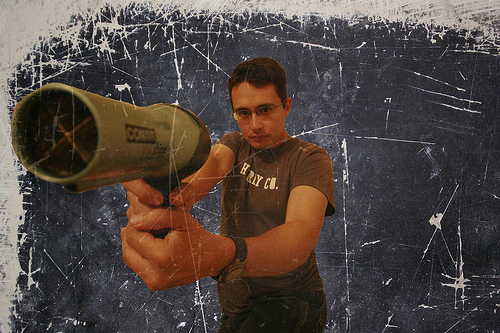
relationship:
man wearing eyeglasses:
[118, 57, 336, 331] [227, 104, 282, 119]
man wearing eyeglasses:
[205, 48, 310, 152] [230, 101, 283, 120]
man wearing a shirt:
[118, 57, 336, 331] [210, 130, 337, 315]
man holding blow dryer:
[118, 57, 336, 331] [9, 73, 216, 201]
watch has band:
[208, 232, 248, 282] [224, 235, 248, 262]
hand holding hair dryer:
[124, 178, 194, 225] [55, 84, 303, 202]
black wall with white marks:
[9, 6, 499, 331] [24, 25, 498, 331]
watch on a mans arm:
[208, 232, 251, 282] [110, 187, 338, 292]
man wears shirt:
[118, 57, 336, 331] [213, 132, 338, 310]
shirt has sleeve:
[213, 132, 338, 310] [289, 143, 335, 213]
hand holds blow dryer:
[119, 180, 194, 225] [10, 82, 211, 243]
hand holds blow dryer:
[118, 208, 215, 290] [10, 82, 211, 243]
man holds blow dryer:
[118, 57, 336, 331] [13, 75, 217, 225]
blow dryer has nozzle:
[9, 73, 216, 201] [6, 82, 113, 191]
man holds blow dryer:
[118, 57, 336, 331] [6, 75, 226, 217]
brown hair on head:
[226, 58, 286, 108] [223, 55, 293, 145]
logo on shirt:
[233, 155, 280, 189] [210, 121, 340, 312]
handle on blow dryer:
[146, 183, 172, 239] [9, 81, 212, 240]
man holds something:
[118, 57, 336, 331] [4, 74, 218, 197]